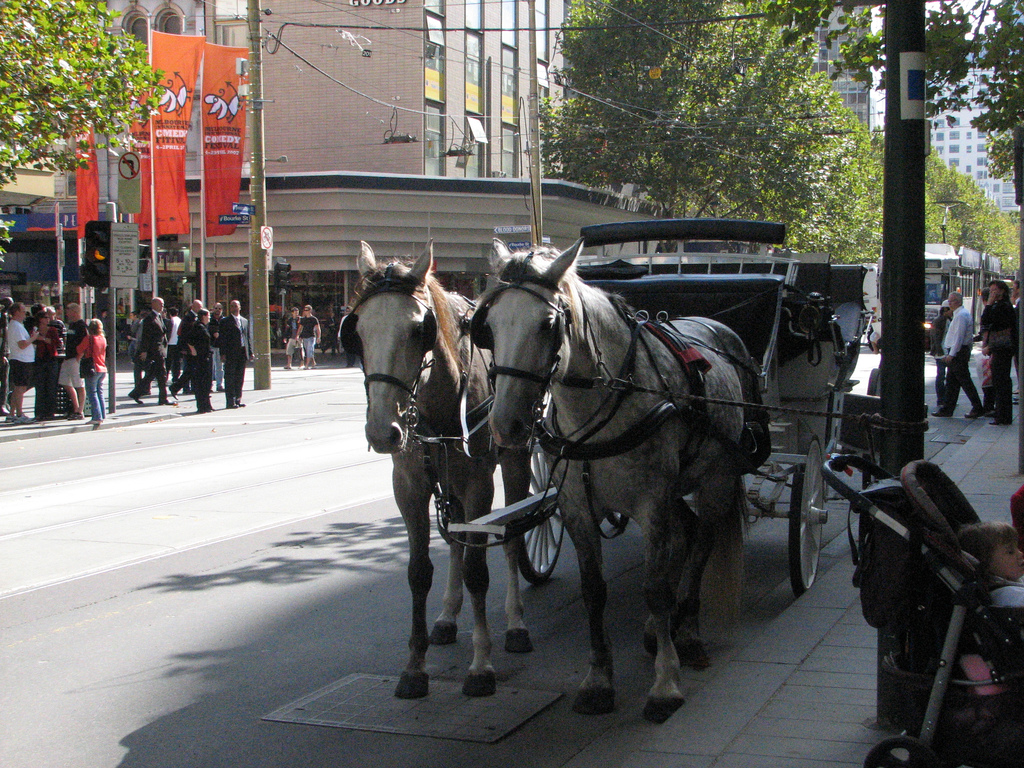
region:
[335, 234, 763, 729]
horse standing next to other horse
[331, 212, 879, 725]
horses in front of white and black carriage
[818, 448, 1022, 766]
child sitting in stroller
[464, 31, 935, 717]
horse tied up to a pole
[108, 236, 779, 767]
shadows underneath the horses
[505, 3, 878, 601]
green leafy tree behind white carriage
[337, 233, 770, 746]
Two white horses pulling a carriage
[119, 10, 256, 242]
two large orange banners with white writing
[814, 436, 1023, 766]
a black stroller with a child in it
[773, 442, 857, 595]
a white and black wheel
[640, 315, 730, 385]
a red cloth on the back of the horse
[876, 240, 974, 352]
a white bus behind the pole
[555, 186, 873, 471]
a black carriage the horses pull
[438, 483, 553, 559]
the white bar between the horses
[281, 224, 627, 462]
a view of horses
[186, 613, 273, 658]
a view of road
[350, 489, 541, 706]
leg of the horse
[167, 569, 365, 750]
a view of shadow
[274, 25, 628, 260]
a view of building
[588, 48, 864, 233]
a view of trees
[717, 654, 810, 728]
lines in the road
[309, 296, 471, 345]
blinders around the horse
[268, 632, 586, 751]
horse's foot on silver panel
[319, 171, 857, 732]
white carraige drawn by horses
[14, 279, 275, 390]
people standing on the sidewalk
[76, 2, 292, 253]
large orange banners in front of building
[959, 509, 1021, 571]
child sitting in stroller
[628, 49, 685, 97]
yellow leaf on tree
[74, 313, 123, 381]
woman wearing pink jacket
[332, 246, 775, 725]
two horses standing on the street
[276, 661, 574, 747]
man hole cover on the street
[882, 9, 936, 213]
the pole has a white and blue sticker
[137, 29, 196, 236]
the banner is orange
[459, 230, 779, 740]
horse on right is white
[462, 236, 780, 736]
white horse pulling carriage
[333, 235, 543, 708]
horse on left is brown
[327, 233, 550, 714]
brown horse pulling carriage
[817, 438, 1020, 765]
brown stroller on sidewalk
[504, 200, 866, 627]
carriage behind two horses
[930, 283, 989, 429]
man stepping off sidewalk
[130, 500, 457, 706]
shadow of trees on street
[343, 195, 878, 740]
horses pulling carriage on street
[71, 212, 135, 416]
black street light on side of street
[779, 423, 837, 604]
white wheel on carriage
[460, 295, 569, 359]
pair of black blinders on horse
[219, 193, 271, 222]
blue street signs on pole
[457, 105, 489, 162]
open window on front of building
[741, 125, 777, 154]
green leaves on the tree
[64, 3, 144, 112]
green leaves on the tree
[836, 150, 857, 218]
green leaves on the tree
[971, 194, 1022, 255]
green leaves on the tree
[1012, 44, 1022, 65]
green leaves on the tree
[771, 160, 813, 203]
green leaves on the tree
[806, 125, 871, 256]
green leaves on the tree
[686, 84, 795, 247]
green leaves on the tree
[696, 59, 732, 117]
green leaves on the tree